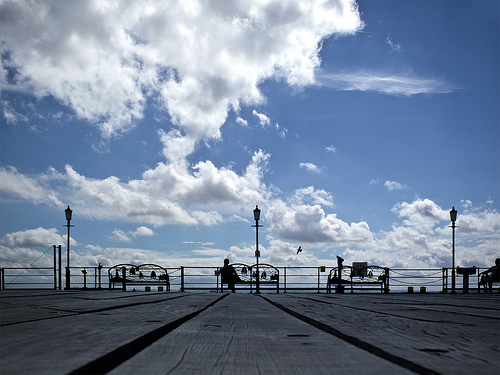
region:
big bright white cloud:
[40, 19, 364, 133]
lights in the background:
[49, 186, 476, 268]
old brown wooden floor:
[62, 288, 467, 373]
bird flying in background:
[283, 233, 338, 268]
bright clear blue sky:
[58, 28, 477, 234]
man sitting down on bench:
[205, 251, 295, 296]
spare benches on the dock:
[282, 255, 498, 296]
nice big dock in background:
[24, 24, 477, 374]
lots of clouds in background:
[40, 57, 469, 264]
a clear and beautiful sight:
[24, 58, 461, 283]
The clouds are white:
[21, 9, 270, 166]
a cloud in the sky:
[234, 161, 274, 201]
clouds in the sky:
[271, 188, 342, 238]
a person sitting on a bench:
[214, 256, 246, 290]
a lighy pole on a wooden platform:
[444, 198, 461, 296]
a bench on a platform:
[105, 266, 176, 293]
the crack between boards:
[166, 308, 206, 345]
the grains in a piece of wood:
[156, 348, 220, 373]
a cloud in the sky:
[364, 67, 412, 106]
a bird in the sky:
[293, 237, 312, 259]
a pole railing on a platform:
[16, 263, 63, 290]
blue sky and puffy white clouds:
[0, 0, 480, 201]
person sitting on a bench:
[206, 246, 291, 296]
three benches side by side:
[85, 250, 415, 287]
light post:
[40, 180, 87, 285]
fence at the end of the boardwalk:
[10, 245, 440, 295]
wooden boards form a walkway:
[65, 290, 445, 356]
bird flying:
[270, 200, 320, 255]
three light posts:
[15, 185, 470, 300]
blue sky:
[330, 105, 490, 165]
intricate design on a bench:
[101, 252, 186, 293]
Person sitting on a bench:
[213, 255, 251, 292]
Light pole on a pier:
[248, 202, 270, 298]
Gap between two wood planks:
[68, 322, 194, 373]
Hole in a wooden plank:
[282, 327, 312, 341]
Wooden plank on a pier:
[194, 297, 289, 373]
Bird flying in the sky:
[293, 243, 309, 253]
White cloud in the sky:
[159, 54, 229, 151]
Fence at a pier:
[4, 267, 111, 289]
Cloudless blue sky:
[376, 107, 499, 167]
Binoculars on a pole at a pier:
[333, 254, 348, 292]